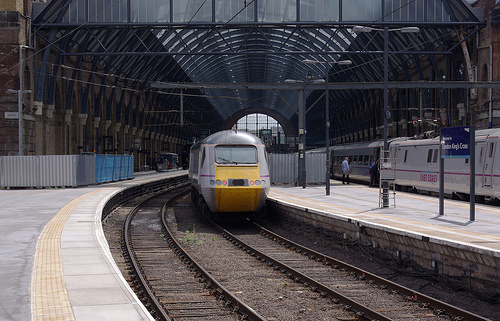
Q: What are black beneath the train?
A: Rails.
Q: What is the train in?
A: Tunnel.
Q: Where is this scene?
A: Subway.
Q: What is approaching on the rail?
A: Train.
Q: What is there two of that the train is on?
A: Railway line.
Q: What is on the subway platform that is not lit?
A: Lampstand.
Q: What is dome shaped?
A: Roof.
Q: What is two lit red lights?
A: Train.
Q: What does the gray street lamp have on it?
A: Two lights.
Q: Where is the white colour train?
A: In the railway station.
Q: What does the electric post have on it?
A: Lamp.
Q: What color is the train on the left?
A: Gray and yellow.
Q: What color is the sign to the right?
A: Blue.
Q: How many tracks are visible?
A: 2.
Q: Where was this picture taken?
A: Train station.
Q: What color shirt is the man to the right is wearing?
A: Blue.